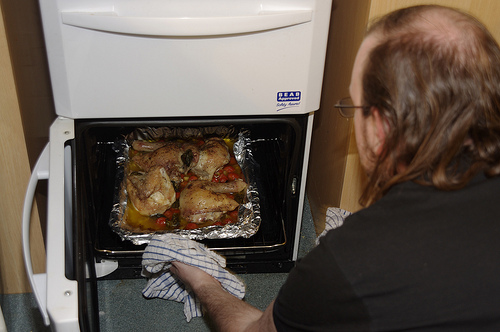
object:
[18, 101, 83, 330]
oven door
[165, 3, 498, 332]
man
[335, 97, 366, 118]
glasses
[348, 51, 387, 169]
face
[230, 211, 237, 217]
carrot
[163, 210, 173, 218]
carrot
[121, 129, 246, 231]
food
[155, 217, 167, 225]
carrot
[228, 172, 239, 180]
carrot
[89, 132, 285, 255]
pan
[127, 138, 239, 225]
chicken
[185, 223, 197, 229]
carrot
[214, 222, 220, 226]
carrot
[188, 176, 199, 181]
carrot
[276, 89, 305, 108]
logo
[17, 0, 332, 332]
oven